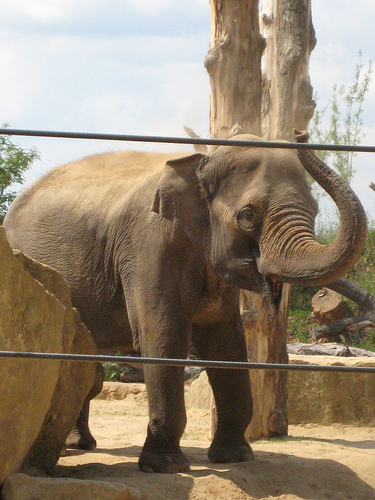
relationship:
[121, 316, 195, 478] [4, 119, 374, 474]
leg of elephant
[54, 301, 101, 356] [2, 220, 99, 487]
edge of wall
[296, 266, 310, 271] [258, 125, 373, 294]
part of a trunk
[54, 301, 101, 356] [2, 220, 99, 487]
edge of a wall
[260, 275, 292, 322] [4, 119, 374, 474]
mouth of a elephant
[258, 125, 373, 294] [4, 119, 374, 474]
trunk of a elephant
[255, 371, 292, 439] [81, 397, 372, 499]
stump on ground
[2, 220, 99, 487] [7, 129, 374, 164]
wall near fence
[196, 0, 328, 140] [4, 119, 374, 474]
tree behind elephant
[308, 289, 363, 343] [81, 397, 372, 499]
tree on ground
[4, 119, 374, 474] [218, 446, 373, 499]
elephant has shadow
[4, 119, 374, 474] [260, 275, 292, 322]
elephant has open mouth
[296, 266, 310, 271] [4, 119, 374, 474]
part of an elephant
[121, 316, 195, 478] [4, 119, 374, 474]
leg of an elephant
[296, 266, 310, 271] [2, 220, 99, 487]
part of wall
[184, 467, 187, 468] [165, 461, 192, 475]
edge of toe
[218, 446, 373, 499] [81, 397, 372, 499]
shadow on ground